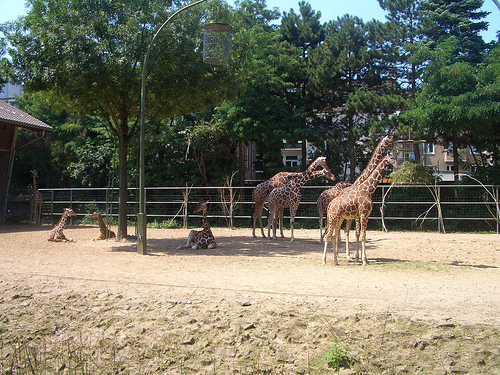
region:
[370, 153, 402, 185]
head of baby giraffe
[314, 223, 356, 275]
back legs of giraffe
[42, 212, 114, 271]
body of baby giraffe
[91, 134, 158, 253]
bark on long tree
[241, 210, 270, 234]
back legs of tall giraffe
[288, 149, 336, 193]
head of tall giraffe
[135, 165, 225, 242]
back white fence in zoo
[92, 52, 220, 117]
top of tall trees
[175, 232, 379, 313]
dirt that giraffes are on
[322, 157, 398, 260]
full body of giraffe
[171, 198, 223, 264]
Giraffe sitting on the ground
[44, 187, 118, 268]
Two Giraffes sitting next to each other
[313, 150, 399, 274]
Giraffes standing next to each other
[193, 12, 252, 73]
Giraffe feeder on a pole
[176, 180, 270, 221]
Metal fence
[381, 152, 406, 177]
Giraffe looking forward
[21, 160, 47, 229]
Giraffe standing next to fence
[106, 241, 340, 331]
Dirt on the ground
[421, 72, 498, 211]
Trees on other side of fence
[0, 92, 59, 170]
Shed for Giraffes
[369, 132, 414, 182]
face of the giraffe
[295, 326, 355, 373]
a small green leaf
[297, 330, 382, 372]
a small green plant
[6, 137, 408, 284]
group of giraffe standing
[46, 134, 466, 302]
group of giraffe sitting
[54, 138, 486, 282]
giraffe standing under the tree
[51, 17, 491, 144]
a group of trees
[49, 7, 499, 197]
beautiful view of trees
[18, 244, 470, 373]
sun shine on the land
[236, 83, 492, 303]
Giraffes in captivity.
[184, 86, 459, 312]
Four giraffes that are in captivity.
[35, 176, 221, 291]
Giraffes lying on the ground.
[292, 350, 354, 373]
Grass on the sand.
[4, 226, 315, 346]
Sand on the ground.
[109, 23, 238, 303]
Light in the ground.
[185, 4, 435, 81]
Trees in the background.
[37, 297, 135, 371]
Pieces of grass on the ground.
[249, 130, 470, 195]
Buildings behind the gate.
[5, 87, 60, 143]
Roof on the building.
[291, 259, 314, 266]
part of a ground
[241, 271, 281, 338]
part of some sand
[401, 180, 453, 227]
part of a fence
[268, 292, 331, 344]
part of a ground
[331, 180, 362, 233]
part of a stmach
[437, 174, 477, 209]
part of a fence